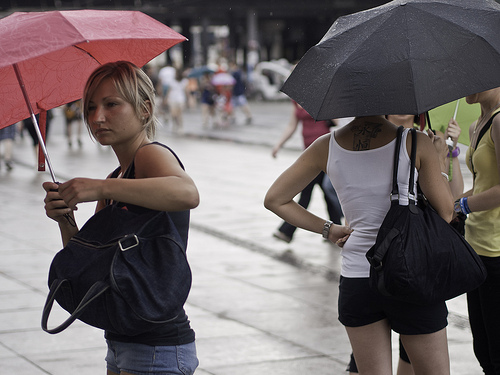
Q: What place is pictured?
A: It is a pavement.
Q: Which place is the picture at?
A: It is at the pavement.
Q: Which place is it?
A: It is a pavement.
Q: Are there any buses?
A: No, there are no buses.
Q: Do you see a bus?
A: No, there are no buses.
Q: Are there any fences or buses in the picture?
A: No, there are no buses or fences.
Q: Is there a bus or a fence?
A: No, there are no buses or fences.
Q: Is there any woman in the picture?
A: Yes, there is a woman.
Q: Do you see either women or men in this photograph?
A: Yes, there is a woman.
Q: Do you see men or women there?
A: Yes, there is a woman.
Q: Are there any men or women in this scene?
A: Yes, there is a woman.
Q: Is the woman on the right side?
A: Yes, the woman is on the right of the image.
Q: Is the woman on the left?
A: No, the woman is on the right of the image.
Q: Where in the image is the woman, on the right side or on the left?
A: The woman is on the right of the image.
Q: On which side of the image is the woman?
A: The woman is on the right of the image.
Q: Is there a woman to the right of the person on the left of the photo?
A: Yes, there is a woman to the right of the person.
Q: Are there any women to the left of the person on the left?
A: No, the woman is to the right of the person.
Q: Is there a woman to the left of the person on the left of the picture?
A: No, the woman is to the right of the person.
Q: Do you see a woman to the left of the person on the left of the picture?
A: No, the woman is to the right of the person.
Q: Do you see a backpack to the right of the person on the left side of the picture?
A: No, there is a woman to the right of the person.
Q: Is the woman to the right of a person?
A: Yes, the woman is to the right of a person.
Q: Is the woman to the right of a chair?
A: No, the woman is to the right of a person.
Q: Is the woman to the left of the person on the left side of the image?
A: No, the woman is to the right of the person.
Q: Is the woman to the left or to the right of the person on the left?
A: The woman is to the right of the person.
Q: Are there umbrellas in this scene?
A: Yes, there is an umbrella.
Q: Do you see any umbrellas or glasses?
A: Yes, there is an umbrella.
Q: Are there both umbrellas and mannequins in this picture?
A: No, there is an umbrella but no mannequins.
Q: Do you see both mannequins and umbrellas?
A: No, there is an umbrella but no mannequins.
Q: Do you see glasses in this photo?
A: No, there are no glasses.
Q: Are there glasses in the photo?
A: No, there are no glasses.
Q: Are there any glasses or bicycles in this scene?
A: No, there are no glasses or bicycles.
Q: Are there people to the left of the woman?
A: Yes, there is a person to the left of the woman.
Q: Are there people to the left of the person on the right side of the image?
A: Yes, there is a person to the left of the woman.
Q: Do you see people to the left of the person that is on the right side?
A: Yes, there is a person to the left of the woman.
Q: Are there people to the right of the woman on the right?
A: No, the person is to the left of the woman.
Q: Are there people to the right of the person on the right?
A: No, the person is to the left of the woman.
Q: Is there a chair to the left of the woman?
A: No, there is a person to the left of the woman.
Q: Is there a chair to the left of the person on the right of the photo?
A: No, there is a person to the left of the woman.